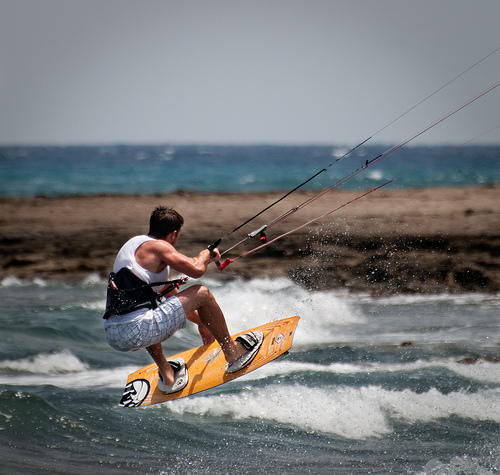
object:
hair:
[148, 203, 185, 241]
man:
[103, 202, 263, 386]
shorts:
[102, 296, 187, 355]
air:
[62, 46, 164, 109]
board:
[118, 313, 300, 412]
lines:
[229, 126, 500, 264]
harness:
[105, 267, 185, 314]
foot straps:
[222, 330, 264, 376]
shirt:
[110, 228, 179, 289]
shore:
[0, 180, 500, 295]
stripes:
[105, 328, 129, 337]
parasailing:
[99, 50, 500, 411]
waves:
[6, 272, 500, 440]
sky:
[0, 0, 500, 146]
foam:
[0, 268, 500, 448]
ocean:
[0, 273, 500, 475]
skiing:
[105, 207, 301, 410]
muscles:
[163, 245, 189, 267]